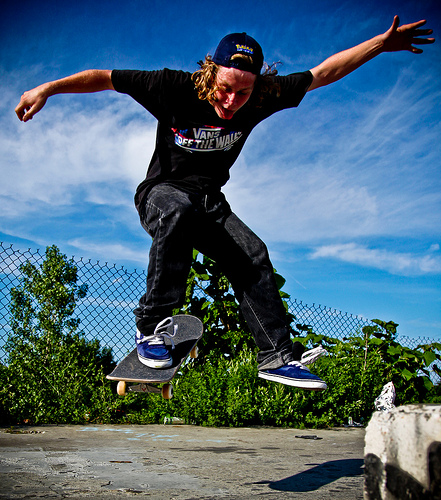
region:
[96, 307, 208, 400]
skateboard in the air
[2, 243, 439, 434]
row of bushes on a fence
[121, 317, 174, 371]
one foot on a skateboard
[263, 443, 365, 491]
shadow of a skateboard on the ground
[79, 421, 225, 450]
blue writing on the ground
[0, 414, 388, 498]
paved area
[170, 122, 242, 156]
writing on the man's shirt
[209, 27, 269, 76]
man's backwards black baseball cap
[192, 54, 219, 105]
man's wavy blond hair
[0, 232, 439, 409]
metal fence behind the man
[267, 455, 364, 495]
The shadow of a skateboard.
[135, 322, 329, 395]
Two blue tennis shoes with white laces.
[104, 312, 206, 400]
A skateboard up in the air.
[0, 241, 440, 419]
A metal fence with bushes in front of it.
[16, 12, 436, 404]
A skateboarder up in the air.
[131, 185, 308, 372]
Dark blue jeans.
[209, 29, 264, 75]
A baseball cap turned backwards.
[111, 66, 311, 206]
A black short sleeved t-shirt.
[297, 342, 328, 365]
White shoe laces.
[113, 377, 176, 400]
Front wheels on a skateboard.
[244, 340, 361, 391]
a blue and white shoe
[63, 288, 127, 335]
the wire mesh is making the fence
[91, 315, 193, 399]
the scateboard is black with orange tyres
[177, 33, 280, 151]
his tongue is out of the mouth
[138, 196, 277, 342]
he is wearing a black denim jeans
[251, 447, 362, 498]
the shadow of the scateboard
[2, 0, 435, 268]
his arms are stretched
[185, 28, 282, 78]
he has a black upturned cap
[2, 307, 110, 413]
plants are growing on the other side of the fence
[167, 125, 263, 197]
his shirt has some writting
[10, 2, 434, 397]
a skater in the air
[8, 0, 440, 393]
skater wears black top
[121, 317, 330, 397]
blue shoes with white pins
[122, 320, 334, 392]
blue shoes with white sole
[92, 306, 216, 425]
a skateboard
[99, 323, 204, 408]
a skateboard in the air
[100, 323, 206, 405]
skateboard is color black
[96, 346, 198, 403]
wheels of skateboard are yellow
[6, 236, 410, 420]
a metal fence behind bushes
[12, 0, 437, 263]
skater has extended arms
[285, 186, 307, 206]
Small patch of a gray cloud in the sky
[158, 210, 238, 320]
Black jeans of the skateboarder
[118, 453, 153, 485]
Small patch of gray concrete ground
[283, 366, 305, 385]
Left blue and white shoe of skateboarder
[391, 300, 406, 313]
Blue part of the sky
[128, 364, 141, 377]
Top black part of skateboard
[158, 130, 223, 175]
Black, red, blue, and white shirt of skateboarder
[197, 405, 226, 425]
Green bush behind the fence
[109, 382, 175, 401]
Front wheels of the skateboard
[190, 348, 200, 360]
Back left wheel of the skateboard